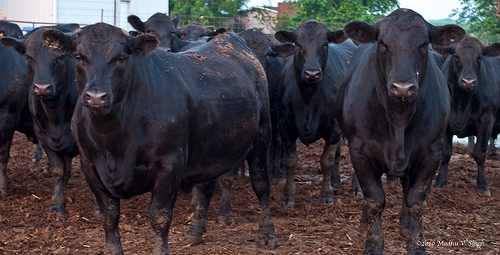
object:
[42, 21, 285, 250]
cow is facing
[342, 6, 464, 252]
cow is black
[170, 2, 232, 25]
trees behind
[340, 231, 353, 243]
wooden chip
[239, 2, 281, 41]
building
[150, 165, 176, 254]
front leg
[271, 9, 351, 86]
head of cow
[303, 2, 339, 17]
green leaves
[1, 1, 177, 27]
wall of a building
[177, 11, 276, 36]
wire mesh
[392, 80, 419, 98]
nose is brown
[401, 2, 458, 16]
sky is bright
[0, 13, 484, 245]
pen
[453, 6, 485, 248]
cows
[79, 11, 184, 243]
cow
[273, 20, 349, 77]
face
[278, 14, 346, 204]
cow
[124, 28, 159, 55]
ear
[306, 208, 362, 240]
soil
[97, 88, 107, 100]
nostril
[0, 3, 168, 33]
cowshed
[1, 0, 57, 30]
door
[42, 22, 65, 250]
cow